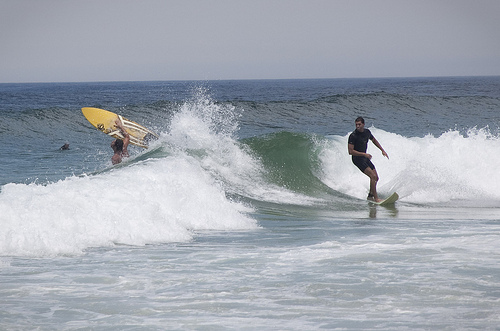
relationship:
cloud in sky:
[1, 24, 172, 70] [0, 0, 499, 84]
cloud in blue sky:
[1, 0, 500, 83] [391, 24, 468, 68]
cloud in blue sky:
[1, 0, 500, 83] [14, 10, 490, 75]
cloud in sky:
[1, 0, 500, 83] [0, 0, 499, 84]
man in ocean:
[101, 115, 134, 168] [0, 75, 500, 331]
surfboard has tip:
[343, 192, 403, 207] [377, 191, 406, 206]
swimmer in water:
[58, 142, 71, 151] [5, 69, 485, 316]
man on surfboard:
[346, 115, 392, 204] [321, 88, 435, 253]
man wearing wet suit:
[346, 115, 392, 204] [348, 129, 375, 169]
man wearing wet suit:
[346, 115, 392, 204] [349, 128, 379, 169]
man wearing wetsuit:
[346, 115, 392, 204] [350, 126, 374, 170]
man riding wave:
[346, 115, 392, 204] [8, 77, 479, 262]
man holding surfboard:
[346, 115, 392, 204] [77, 99, 167, 154]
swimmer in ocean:
[59, 138, 71, 151] [2, 75, 499, 327]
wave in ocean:
[105, 108, 346, 225] [75, 54, 337, 164]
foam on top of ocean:
[2, 234, 498, 330] [0, 75, 500, 331]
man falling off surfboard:
[346, 115, 392, 204] [81, 100, 163, 146]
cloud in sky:
[1, 0, 500, 83] [3, 3, 484, 103]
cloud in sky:
[1, 0, 500, 83] [3, 4, 499, 76]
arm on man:
[347, 143, 370, 158] [346, 115, 392, 204]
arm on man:
[366, 129, 390, 159] [346, 115, 392, 204]